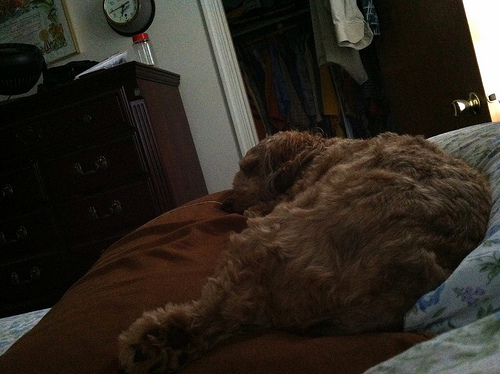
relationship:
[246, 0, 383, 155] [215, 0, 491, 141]
clothes hanging in closet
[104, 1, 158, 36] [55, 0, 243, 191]
clock hanging on wall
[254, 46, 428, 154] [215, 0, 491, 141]
clothes hanging in closet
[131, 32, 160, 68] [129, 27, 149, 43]
bottle has a top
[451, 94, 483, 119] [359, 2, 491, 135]
handle to closet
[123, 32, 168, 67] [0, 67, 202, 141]
bottle on table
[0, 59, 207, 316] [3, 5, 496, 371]
cabinet in room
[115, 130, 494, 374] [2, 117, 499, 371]
brown dog laying on bed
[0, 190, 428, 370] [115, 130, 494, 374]
brown blanket under brown dog